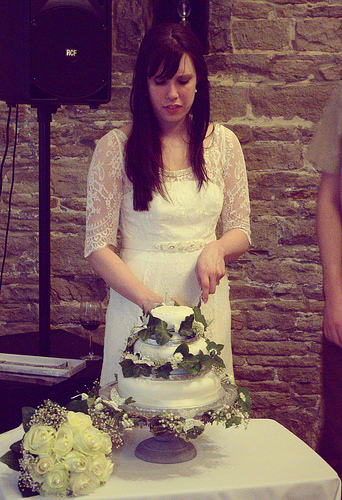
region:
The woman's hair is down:
[126, 25, 216, 178]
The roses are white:
[18, 417, 99, 493]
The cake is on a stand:
[100, 391, 254, 482]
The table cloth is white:
[218, 442, 333, 498]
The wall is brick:
[242, 251, 284, 398]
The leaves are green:
[214, 384, 271, 448]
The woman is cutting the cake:
[90, 235, 236, 347]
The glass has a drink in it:
[68, 294, 122, 399]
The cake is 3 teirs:
[141, 309, 216, 424]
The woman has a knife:
[177, 255, 243, 336]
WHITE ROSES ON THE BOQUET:
[27, 405, 122, 482]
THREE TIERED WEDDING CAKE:
[95, 307, 250, 466]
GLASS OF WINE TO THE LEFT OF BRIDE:
[75, 294, 105, 364]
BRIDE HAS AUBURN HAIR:
[109, 25, 227, 188]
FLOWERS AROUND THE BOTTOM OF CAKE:
[69, 381, 256, 431]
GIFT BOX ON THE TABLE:
[2, 356, 93, 379]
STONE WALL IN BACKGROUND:
[214, 12, 328, 101]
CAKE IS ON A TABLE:
[1, 397, 329, 497]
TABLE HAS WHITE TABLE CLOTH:
[7, 397, 339, 496]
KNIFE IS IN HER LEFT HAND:
[168, 215, 252, 340]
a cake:
[67, 277, 263, 497]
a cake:
[130, 298, 228, 483]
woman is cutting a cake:
[78, 20, 253, 420]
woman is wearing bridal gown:
[83, 24, 252, 413]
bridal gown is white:
[81, 120, 252, 414]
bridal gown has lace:
[82, 118, 253, 406]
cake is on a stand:
[102, 298, 236, 463]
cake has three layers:
[104, 303, 235, 419]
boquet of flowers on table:
[2, 397, 116, 498]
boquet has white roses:
[5, 400, 121, 498]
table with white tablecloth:
[5, 405, 340, 498]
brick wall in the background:
[6, 7, 326, 422]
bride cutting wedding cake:
[81, 21, 263, 475]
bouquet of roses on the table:
[1, 396, 121, 498]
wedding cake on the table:
[101, 304, 265, 472]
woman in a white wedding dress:
[88, 30, 263, 291]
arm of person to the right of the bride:
[315, 93, 341, 347]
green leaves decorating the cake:
[117, 342, 221, 381]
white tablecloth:
[3, 411, 339, 498]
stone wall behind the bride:
[6, 0, 316, 428]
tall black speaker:
[12, 0, 118, 364]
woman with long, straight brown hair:
[115, 25, 221, 213]